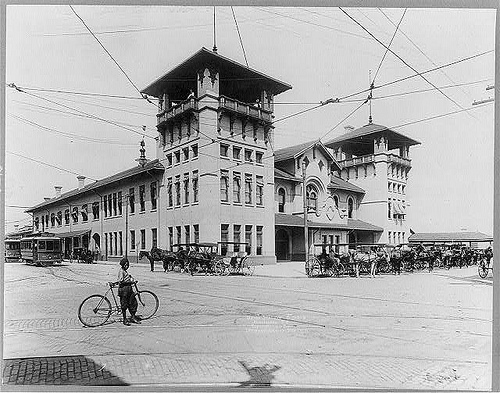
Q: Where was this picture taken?
A: In front of a building.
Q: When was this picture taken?
A: During the day.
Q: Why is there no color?
A: Its a black and white picture.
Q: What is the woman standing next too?
A: A bicycle.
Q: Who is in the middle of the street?
A: The woman.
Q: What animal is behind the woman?
A: A horse.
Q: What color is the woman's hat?
A: Black.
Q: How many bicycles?
A: One.